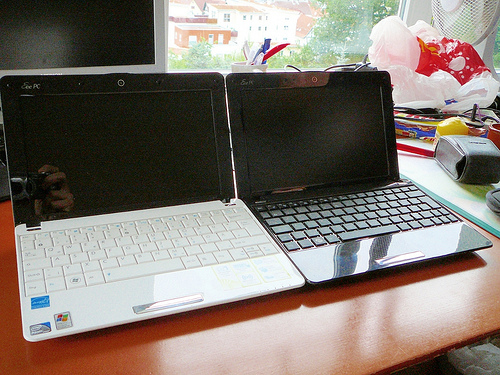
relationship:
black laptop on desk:
[225, 70, 493, 285] [0, 180, 500, 375]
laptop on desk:
[1, 59, 303, 340] [0, 180, 500, 375]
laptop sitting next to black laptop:
[1, 59, 303, 340] [225, 70, 493, 285]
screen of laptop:
[20, 88, 220, 215] [81, 41, 258, 307]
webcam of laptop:
[115, 77, 126, 88] [1, 72, 307, 344]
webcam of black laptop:
[309, 74, 319, 82] [225, 70, 493, 285]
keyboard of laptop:
[17, 205, 277, 295] [1, 59, 303, 340]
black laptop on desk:
[225, 70, 493, 285] [7, 181, 492, 374]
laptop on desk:
[1, 59, 303, 340] [7, 181, 492, 374]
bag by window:
[362, 5, 499, 122] [163, 9, 497, 112]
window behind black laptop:
[163, 9, 497, 112] [225, 70, 493, 285]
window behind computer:
[163, 9, 497, 112] [1, 68, 303, 348]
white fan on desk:
[427, 1, 499, 88] [7, 181, 492, 374]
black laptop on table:
[225, 70, 493, 285] [0, 154, 498, 374]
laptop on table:
[1, 59, 303, 340] [0, 154, 498, 374]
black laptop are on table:
[225, 70, 493, 285] [202, 312, 455, 346]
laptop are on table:
[1, 72, 307, 344] [202, 312, 455, 346]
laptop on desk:
[1, 72, 307, 344] [0, 180, 500, 375]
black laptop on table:
[225, 72, 494, 289] [248, 301, 489, 361]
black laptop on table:
[225, 70, 493, 285] [229, 316, 459, 374]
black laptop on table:
[225, 70, 493, 285] [252, 293, 493, 363]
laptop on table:
[1, 59, 303, 340] [171, 313, 426, 373]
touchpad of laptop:
[133, 292, 203, 314] [1, 59, 303, 340]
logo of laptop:
[17, 78, 47, 96] [1, 59, 303, 340]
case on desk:
[430, 132, 499, 186] [16, 103, 458, 373]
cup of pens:
[211, 34, 296, 91] [235, 31, 325, 80]